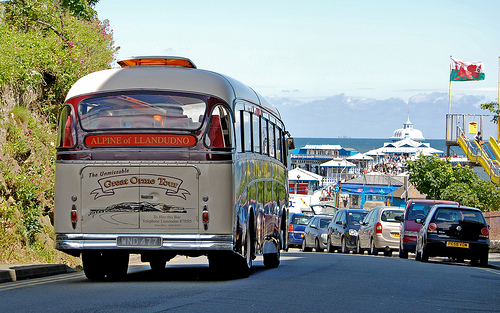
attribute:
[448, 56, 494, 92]
flag — white, green, red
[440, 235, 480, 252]
plate — yellow, license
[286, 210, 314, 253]
vehicle — blue, parked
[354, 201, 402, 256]
minivan — gray, parked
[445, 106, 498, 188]
rail — yellow, lined, stair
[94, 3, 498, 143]
sky — pale blue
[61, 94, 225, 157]
window — rear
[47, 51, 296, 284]
bus — old, beige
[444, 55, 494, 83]
flag — green, red, white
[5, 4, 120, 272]
trees — green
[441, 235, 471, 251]
plate — yellow, license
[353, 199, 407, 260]
car — gray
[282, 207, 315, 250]
car — blue 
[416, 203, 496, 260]
car — Black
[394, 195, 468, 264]
truck — red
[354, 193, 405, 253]
car — silver 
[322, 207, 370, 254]
car — black 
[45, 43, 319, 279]
bus — white 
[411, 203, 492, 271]
car — black , parked 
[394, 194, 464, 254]
van — parked , red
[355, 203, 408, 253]
van — parked , silver 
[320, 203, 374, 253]
car — parked , black 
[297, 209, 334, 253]
car — silver , parked 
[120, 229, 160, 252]
license plate — grey , white 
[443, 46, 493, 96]
flag — waving 